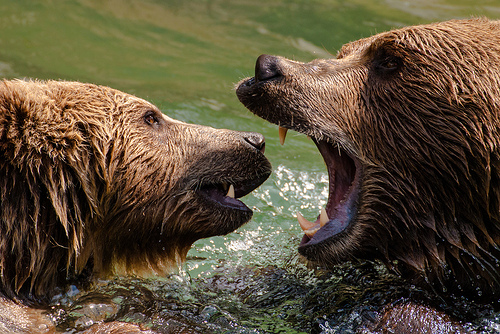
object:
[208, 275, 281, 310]
water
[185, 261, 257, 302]
water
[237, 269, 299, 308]
water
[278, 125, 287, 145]
teeth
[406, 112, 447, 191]
fur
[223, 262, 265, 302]
bubbles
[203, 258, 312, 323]
surface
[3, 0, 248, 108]
water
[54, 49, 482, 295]
bears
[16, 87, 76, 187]
fur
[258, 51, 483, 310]
bear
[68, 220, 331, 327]
water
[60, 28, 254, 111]
water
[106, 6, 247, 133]
water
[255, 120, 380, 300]
mouth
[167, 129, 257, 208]
mouth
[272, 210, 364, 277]
teeth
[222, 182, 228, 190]
tooth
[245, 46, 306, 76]
nose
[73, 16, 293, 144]
water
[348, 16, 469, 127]
eye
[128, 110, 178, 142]
eye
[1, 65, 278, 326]
bear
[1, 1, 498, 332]
water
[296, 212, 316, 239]
tooth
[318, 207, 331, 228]
tooth